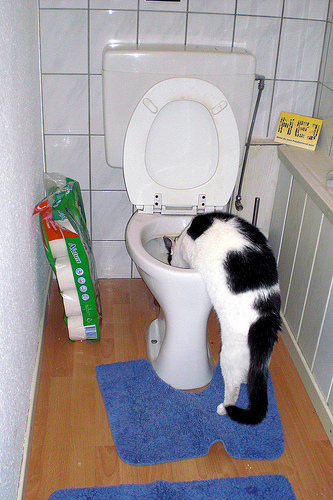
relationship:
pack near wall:
[31, 172, 102, 344] [0, 12, 44, 400]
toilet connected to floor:
[102, 42, 256, 391] [128, 331, 214, 435]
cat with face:
[139, 205, 314, 412] [161, 251, 191, 263]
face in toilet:
[161, 251, 191, 263] [115, 222, 237, 412]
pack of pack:
[31, 172, 102, 344] [31, 172, 102, 344]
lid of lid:
[123, 72, 242, 225] [123, 75, 241, 205]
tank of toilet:
[102, 43, 254, 168] [102, 42, 256, 391]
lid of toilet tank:
[102, 43, 255, 73] [102, 43, 254, 167]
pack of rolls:
[31, 172, 102, 344] [42, 227, 95, 259]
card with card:
[272, 109, 321, 150] [273, 111, 323, 150]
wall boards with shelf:
[266, 147, 332, 450] [276, 142, 332, 223]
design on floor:
[40, 366, 101, 443] [37, 281, 331, 492]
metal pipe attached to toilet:
[235, 74, 265, 212] [110, 39, 278, 312]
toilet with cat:
[102, 42, 256, 391] [158, 208, 291, 432]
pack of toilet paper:
[29, 165, 111, 352] [28, 147, 138, 344]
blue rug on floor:
[94, 357, 286, 467] [37, 281, 331, 492]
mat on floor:
[49, 475, 292, 499] [37, 281, 331, 492]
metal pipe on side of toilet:
[245, 85, 260, 168] [124, 75, 254, 417]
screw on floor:
[150, 334, 158, 349] [37, 281, 331, 492]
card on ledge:
[273, 111, 323, 150] [297, 156, 315, 171]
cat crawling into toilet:
[167, 210, 286, 425] [102, 42, 256, 391]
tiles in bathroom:
[39, 10, 315, 139] [0, 0, 332, 498]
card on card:
[273, 111, 323, 150] [273, 111, 323, 150]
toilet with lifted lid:
[104, 62, 274, 267] [111, 76, 252, 180]